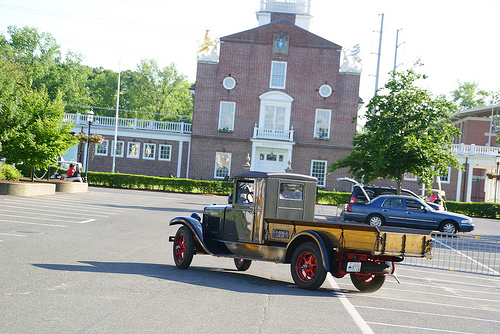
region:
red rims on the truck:
[299, 243, 320, 275]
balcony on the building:
[249, 120, 298, 145]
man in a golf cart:
[63, 158, 77, 178]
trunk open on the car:
[332, 168, 370, 217]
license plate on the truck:
[346, 257, 365, 281]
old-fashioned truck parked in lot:
[3, 167, 491, 326]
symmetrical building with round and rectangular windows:
[186, 9, 365, 196]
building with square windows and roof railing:
[57, 109, 192, 186]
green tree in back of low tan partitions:
[3, 20, 86, 197]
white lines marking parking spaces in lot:
[5, 190, 495, 327]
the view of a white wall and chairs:
[290, 273, 315, 277]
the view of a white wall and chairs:
[295, 275, 305, 292]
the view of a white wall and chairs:
[274, 243, 281, 274]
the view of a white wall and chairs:
[296, 275, 333, 280]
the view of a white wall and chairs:
[270, 245, 279, 289]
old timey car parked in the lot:
[174, 171, 427, 290]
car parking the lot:
[342, 187, 472, 243]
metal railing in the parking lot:
[382, 221, 499, 282]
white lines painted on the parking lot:
[308, 194, 499, 330]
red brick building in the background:
[88, 5, 495, 206]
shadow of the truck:
[24, 247, 339, 299]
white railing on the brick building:
[66, 107, 186, 141]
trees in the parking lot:
[8, 44, 445, 184]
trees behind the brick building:
[3, 18, 498, 146]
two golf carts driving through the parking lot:
[42, 157, 445, 217]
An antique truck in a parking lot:
[169, 167, 429, 291]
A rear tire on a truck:
[288, 244, 328, 290]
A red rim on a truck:
[298, 254, 314, 278]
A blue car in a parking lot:
[349, 193, 473, 233]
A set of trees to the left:
[6, 23, 193, 200]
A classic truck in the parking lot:
[162, 155, 434, 307]